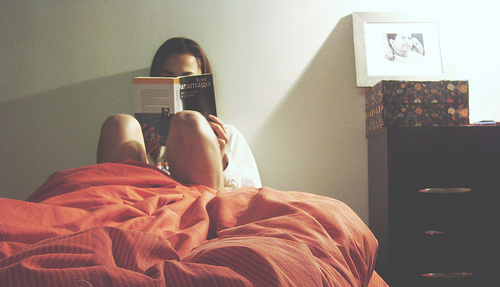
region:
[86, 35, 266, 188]
Woman sitting on bed reading a book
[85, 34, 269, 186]
Woman leaning against wall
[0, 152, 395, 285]
Orange comforter on legs of woman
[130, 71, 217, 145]
Book woman is reading is opened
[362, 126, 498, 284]
Black dressed next to woman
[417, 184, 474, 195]
Silver handle on black dresser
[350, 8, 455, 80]
White picture frame leaning against wall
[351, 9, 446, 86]
White picture frame on top of floral box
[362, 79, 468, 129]
Floral box on top of black dresser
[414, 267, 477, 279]
Silver handle on black dresser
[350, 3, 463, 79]
the picture is on the box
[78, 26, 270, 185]
the girl is reading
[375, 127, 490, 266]
the drawers are black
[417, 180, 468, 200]
the handles are silver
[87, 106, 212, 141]
her knees are bent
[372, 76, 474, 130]
the box is multi-colored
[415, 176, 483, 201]
the handle is silver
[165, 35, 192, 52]
the girl has hair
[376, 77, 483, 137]
the box is on the cabinette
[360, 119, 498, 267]
the cabinette is rectangular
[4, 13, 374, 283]
a woman in bed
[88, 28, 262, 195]
the woman is reading a book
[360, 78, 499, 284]
a box on the stand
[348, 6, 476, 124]
a picture on the box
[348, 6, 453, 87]
a picture in a frame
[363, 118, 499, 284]
the stand is black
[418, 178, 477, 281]
the handles on the stand are silver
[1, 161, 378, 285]
the comforter is red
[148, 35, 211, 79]
the woman has brown hair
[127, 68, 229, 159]
the woman's hands are on the book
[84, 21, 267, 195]
a young woman sitting in bed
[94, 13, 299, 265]
a young woman reading a book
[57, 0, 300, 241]
young woman read a book in bed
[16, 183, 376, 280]
red comforter on a bed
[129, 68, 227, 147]
a paperback book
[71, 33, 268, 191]
a girl reading a paperback book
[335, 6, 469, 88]
a picture frame with a personal photo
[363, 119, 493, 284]
a black dresser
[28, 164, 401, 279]
a disheveled comforter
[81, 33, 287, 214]
a woman relaxing with a book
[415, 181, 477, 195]
Silver handle on a drawer.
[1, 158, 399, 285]
Orange comforter on bed.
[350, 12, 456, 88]
Picture frame sitting on colorful box.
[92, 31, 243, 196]
Woman reading a book in bed.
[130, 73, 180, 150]
Back cover of a book.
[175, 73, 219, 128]
Front cover a book.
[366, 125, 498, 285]
Night stand with drawers.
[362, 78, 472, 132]
Multi-colored box on top of night stand.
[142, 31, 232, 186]
A lady in bed with brown hair.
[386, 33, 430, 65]
Black and white picture in picture frame.